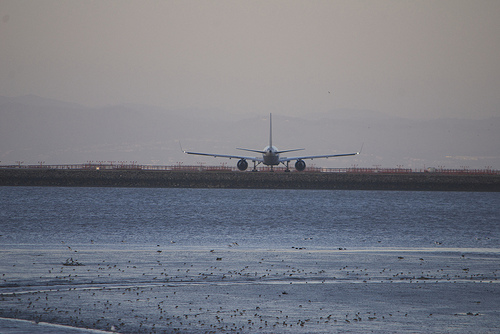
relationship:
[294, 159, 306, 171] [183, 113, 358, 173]
engine of an airplane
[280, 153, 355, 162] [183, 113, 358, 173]
wing of airplane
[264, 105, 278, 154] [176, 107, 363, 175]
tail wing on plane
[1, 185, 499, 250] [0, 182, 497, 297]
waves in water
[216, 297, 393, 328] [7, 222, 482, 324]
sand on beach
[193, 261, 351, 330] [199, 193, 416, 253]
birds in water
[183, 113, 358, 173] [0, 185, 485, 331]
airplane flying over water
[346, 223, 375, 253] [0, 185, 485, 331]
part of water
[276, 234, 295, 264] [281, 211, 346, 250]
part of water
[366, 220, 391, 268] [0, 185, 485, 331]
part of water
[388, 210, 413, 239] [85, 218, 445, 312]
part of water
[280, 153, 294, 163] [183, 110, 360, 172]
part of plane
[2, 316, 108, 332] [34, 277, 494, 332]
edge of shore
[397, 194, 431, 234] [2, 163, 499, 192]
part of shore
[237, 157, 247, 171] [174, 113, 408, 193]
engine of plane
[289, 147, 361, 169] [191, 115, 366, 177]
wing on plane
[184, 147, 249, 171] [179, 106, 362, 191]
wing on plane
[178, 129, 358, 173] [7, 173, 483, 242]
plane on top of water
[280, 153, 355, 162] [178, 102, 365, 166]
wing on plane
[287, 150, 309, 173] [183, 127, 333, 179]
propeller on plane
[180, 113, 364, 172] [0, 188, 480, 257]
airplane over water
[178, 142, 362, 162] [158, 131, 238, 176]
lights on wing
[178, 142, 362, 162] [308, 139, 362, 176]
lights on wing